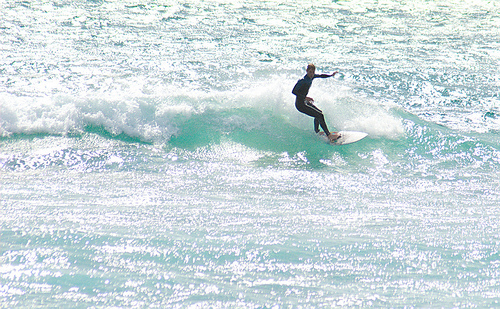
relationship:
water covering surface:
[7, 4, 497, 306] [17, 167, 485, 284]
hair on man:
[306, 63, 316, 72] [288, 59, 337, 139]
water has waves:
[7, 4, 497, 306] [17, 46, 275, 156]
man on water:
[291, 56, 345, 141] [54, 64, 274, 283]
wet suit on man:
[294, 76, 326, 128] [289, 62, 343, 144]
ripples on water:
[4, 3, 481, 301] [7, 4, 497, 306]